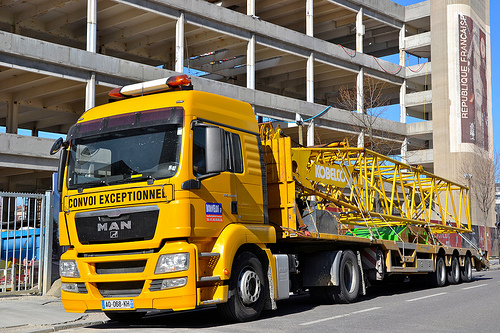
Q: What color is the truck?
A: Yellow.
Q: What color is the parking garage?
A: White.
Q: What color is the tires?
A: Black.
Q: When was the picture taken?
A: In the daytime.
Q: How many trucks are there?
A: 1.